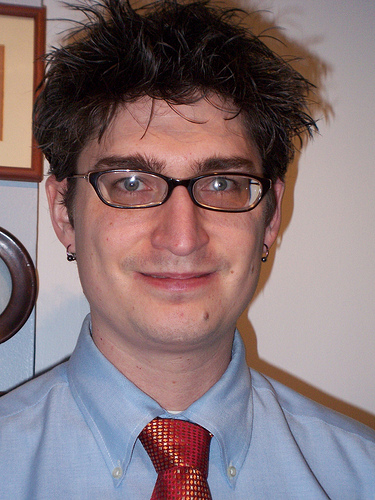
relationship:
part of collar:
[66, 312, 252, 487] [66, 312, 254, 490]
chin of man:
[132, 302, 224, 346] [1, 1, 374, 499]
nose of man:
[150, 198, 209, 257] [1, 1, 374, 499]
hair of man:
[32, 1, 320, 178] [1, 1, 374, 499]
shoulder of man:
[1, 362, 74, 499] [1, 1, 374, 499]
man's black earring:
[1, 1, 374, 499] [259, 243, 270, 264]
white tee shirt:
[166, 409, 182, 416] [167, 410, 185, 413]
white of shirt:
[166, 409, 182, 416] [167, 410, 185, 413]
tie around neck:
[138, 419, 211, 500] [66, 312, 252, 487]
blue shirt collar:
[66, 312, 252, 487] [66, 312, 254, 490]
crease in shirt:
[260, 375, 328, 499] [0, 313, 374, 499]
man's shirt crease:
[1, 1, 374, 499] [260, 375, 328, 499]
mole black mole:
[203, 311, 209, 321] [201, 312, 209, 322]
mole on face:
[201, 312, 209, 322] [71, 94, 264, 348]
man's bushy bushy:
[1, 1, 374, 499] [194, 153, 256, 169]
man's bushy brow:
[1, 1, 374, 499] [92, 152, 165, 173]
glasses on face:
[68, 167, 274, 213] [71, 94, 264, 348]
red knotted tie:
[138, 419, 213, 479] [138, 419, 211, 500]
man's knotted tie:
[1, 1, 374, 499] [138, 419, 211, 500]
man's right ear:
[1, 1, 374, 499] [45, 176, 77, 254]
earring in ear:
[65, 245, 76, 262] [45, 176, 77, 254]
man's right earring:
[1, 1, 374, 499] [65, 245, 76, 262]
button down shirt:
[168, 414, 180, 421] [167, 410, 185, 413]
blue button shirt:
[1, 399, 139, 500] [0, 313, 374, 499]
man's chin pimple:
[1, 1, 374, 499] [201, 312, 209, 322]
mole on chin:
[203, 311, 209, 321] [132, 302, 224, 346]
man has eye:
[1, 1, 374, 499] [114, 175, 154, 193]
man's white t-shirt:
[1, 1, 374, 499] [166, 409, 182, 416]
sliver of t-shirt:
[168, 409, 180, 413] [166, 409, 182, 416]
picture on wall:
[1, 3, 47, 182] [7, 184, 41, 226]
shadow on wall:
[230, 6, 340, 83] [259, 1, 374, 52]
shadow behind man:
[230, 6, 340, 83] [1, 1, 374, 499]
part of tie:
[138, 419, 211, 500] [138, 419, 211, 500]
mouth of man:
[136, 269, 217, 292] [1, 1, 374, 499]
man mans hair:
[1, 1, 374, 499] [32, 1, 320, 178]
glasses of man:
[68, 167, 274, 213] [1, 1, 374, 499]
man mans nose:
[1, 1, 374, 499] [150, 198, 209, 257]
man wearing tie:
[1, 1, 374, 499] [138, 419, 211, 500]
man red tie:
[1, 1, 374, 499] [138, 419, 211, 500]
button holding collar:
[110, 466, 127, 483] [66, 312, 254, 490]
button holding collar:
[225, 462, 240, 483] [66, 312, 254, 490]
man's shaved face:
[1, 1, 374, 499] [71, 94, 264, 348]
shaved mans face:
[74, 255, 261, 350] [71, 94, 264, 348]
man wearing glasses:
[1, 1, 374, 499] [68, 167, 274, 213]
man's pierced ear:
[66, 245, 270, 263] [45, 176, 77, 254]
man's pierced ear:
[45, 176, 77, 254] [44, 175, 79, 263]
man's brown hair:
[1, 1, 374, 499] [32, 1, 320, 178]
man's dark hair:
[1, 1, 374, 499] [32, 1, 320, 178]